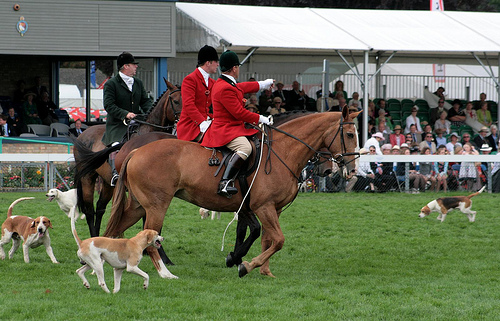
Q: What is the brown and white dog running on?
A: Grass.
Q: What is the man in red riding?
A: A horse.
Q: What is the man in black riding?
A: A horse.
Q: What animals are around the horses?
A: Dogs.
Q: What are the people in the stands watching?
A: The horse riding.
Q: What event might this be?
A: Equestrian.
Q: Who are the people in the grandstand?
A: The spectators.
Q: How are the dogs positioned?
A: Around the horses.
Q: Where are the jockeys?
A: On the horses.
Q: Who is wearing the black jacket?
A: The rider furthest away.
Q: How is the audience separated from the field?
A: By a fence.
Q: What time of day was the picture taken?
A: During daytime.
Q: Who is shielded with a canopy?
A: The audience.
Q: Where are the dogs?
A: On the grass.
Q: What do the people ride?
A: Horses.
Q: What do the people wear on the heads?
A: Black hats.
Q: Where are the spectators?
A: Under the awning.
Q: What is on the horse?
A: A bridal.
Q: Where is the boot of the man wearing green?
A: In the stirrup.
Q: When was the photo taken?
A: During the daytime.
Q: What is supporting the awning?
A: A beam.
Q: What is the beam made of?
A: Metal.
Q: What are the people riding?
A: Horses.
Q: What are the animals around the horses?
A: Dogs.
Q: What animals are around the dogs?
A: Horses.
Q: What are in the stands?
A: Spectators.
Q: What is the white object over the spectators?
A: A roof.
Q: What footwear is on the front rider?
A: Black boots.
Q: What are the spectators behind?
A: A fence.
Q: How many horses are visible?
A: 3.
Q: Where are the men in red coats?
A: Horseback.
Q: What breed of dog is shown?
A: Beagle.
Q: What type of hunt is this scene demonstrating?
A: Fox hunting.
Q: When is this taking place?
A: Daytime.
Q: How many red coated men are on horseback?
A: 2.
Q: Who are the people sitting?
A: Spectators.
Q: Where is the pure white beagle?
A: Behind black coated rider.